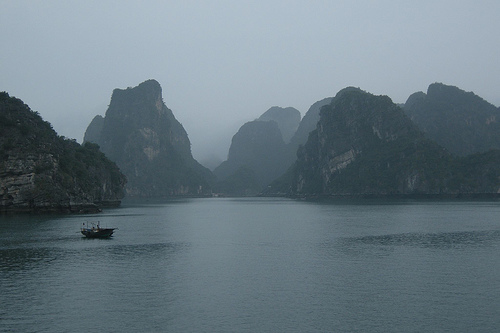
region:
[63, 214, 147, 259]
Boat in the water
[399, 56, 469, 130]
Large rock in the water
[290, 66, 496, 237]
Large rock in the water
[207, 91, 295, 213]
Large rock in the water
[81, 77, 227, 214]
Large rock in the water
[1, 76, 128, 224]
Large rock in the water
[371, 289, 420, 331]
Ripples in the water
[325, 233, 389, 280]
Ripples in the water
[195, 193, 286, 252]
Ripples in the water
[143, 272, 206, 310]
Ripples in the water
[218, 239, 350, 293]
calm black water of the lake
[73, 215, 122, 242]
a small boat on the lake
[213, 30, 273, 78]
cloudy grey skies over the lake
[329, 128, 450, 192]
trees growing on the side of a hill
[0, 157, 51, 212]
rock face of the cliff wall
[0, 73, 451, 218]
several stone hills in the water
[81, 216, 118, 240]
a wood fishing boat on the lake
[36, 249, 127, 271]
ripples from the wind on the water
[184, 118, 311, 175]
mist floating between the hills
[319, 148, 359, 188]
tan rock face of the hill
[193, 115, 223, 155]
fog, smog or marine layer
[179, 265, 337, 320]
calm water with ripples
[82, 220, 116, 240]
small ship on water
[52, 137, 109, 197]
trees and shrubs growing on rocks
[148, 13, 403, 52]
fogged sky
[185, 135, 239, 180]
narrow valley between two hills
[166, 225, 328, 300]
water is not clear, but rather murky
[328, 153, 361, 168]
smooth area of rock with no trees/grass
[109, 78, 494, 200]
collection of rock formations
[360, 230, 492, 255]
shadow above the water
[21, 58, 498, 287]
large rock formations on the water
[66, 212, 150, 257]
a small boat traveling through the area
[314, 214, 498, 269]
waves in the water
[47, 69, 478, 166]
fog on the rock formations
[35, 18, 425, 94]
the sky is cloudy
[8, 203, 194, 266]
waves near the boat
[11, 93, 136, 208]
trees on the rocks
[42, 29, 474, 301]
this scene has a grayish color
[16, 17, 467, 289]
there is mist in this area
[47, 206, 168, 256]
this boat is sailing alone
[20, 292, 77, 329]
Ripples in the water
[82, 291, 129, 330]
Ripples in the water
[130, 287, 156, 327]
Ripples in the water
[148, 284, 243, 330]
Ripples in the water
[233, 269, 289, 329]
Ripples in the water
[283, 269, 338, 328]
Ripples in the water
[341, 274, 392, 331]
Ripples in the water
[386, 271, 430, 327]
Ripples in the water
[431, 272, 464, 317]
Ripples in the water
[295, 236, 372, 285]
Ripples in the water